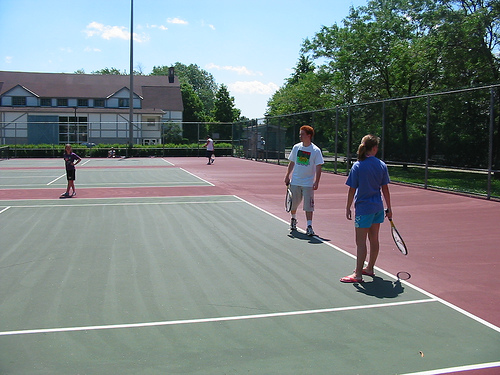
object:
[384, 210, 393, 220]
hand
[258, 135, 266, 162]
person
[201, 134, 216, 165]
person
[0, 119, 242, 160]
fence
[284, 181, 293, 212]
tennis racket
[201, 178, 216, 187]
line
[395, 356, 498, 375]
line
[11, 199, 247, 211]
line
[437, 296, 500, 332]
line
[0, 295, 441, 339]
line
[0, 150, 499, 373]
court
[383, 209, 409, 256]
racket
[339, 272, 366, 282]
flip flops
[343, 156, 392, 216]
shirt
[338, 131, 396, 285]
female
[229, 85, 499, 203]
fence